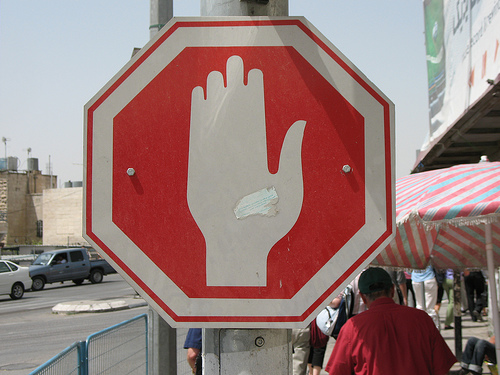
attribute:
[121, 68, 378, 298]
sign — red, white, large, hand, big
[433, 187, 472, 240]
umbrella — pink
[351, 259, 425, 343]
man — walking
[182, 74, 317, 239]
hand — white